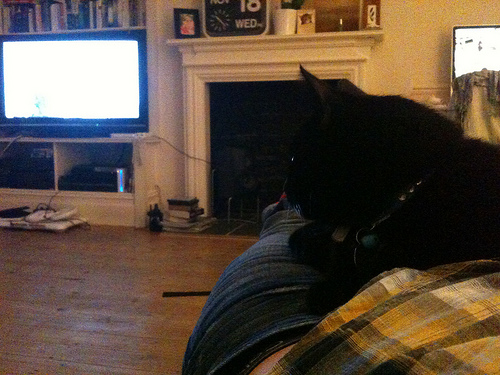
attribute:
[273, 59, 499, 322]
cat — black, relaxing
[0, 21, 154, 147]
television — flat screen, on, big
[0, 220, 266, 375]
floor — brown, wood, wooden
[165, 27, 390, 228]
fireplace — white, black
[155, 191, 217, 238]
books — piled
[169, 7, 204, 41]
frame — black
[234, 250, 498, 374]
shirt — black, gold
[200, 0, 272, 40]
clock — black, white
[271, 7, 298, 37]
flower pot — white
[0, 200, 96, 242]
items — entertainment boxes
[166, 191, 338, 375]
jeans — blue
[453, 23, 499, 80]
window — bright